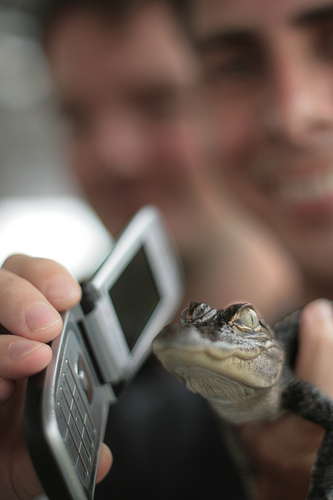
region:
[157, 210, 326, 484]
One man is holding snake in one hand.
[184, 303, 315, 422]
Snake is brown color.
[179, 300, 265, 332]
Eyes are yellow color.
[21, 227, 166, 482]
cell phone is grey and black color.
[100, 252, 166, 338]
Cell phone screen is off.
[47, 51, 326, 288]
Two people are behind the snake.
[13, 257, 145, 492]
One man is holding the cellphone in hand.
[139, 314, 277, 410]
Snake mouth is closed.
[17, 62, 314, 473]
Day time picture.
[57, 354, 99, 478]
Cell phone controls are grey color.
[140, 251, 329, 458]
an alligator being held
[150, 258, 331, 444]
an alligator in a hand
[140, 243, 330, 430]
a baby alligator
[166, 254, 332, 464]
a baby alligator being held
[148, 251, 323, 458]
a baby alligator in a hand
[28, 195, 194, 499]
a silver flip phone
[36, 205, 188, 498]
a flip cell phone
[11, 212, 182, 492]
a hand holding a phone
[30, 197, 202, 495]
a silver cell pohne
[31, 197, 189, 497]
a flip phone open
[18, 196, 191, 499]
The cell phone next to the reptile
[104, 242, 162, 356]
The screen of the phone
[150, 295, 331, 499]
The tiny alligator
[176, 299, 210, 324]
The alligator's right eye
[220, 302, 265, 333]
The alligator's left eye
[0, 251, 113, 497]
The hand holding the phone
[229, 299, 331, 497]
The hand holding the alligator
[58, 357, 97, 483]
The numbered buttons on the phone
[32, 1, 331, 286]
The blurry faces of the men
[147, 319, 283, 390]
The snout of the alligator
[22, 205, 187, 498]
a flip phone in a person's hand.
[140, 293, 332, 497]
A dinosaur in a person's hand.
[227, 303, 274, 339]
the left eye of a lizard.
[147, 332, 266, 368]
the mouth of a lizard.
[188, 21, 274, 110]
the right eye of a human.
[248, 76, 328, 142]
a human nose.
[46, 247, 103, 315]
right pointer finger.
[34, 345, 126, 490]
a keypad on a phone.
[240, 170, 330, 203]
a white smile on a man.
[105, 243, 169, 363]
an lcd screen on a phone.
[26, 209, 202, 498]
silver flip phone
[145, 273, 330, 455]
frog held in a hand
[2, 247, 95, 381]
fingers on the top of the phone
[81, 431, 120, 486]
thumb supporting the bottom of the phone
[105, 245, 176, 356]
the screen is black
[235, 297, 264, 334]
large green eye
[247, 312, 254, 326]
black slit on the eye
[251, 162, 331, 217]
smile exposing teeth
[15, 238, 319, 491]
frog next to a phone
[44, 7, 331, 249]
two men in the background